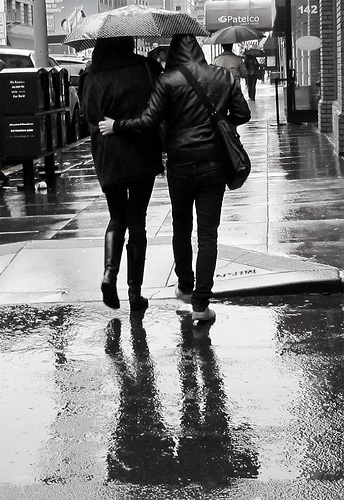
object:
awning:
[204, 1, 273, 33]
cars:
[0, 48, 81, 158]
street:
[260, 122, 327, 202]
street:
[9, 293, 339, 370]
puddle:
[2, 311, 69, 412]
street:
[0, 291, 342, 449]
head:
[89, 35, 135, 66]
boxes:
[0, 67, 70, 159]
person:
[77, 34, 163, 317]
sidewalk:
[0, 79, 343, 303]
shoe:
[190, 307, 218, 320]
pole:
[31, 0, 48, 70]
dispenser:
[0, 66, 70, 187]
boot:
[101, 227, 125, 309]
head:
[165, 34, 208, 69]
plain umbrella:
[199, 25, 266, 47]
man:
[211, 36, 249, 96]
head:
[221, 42, 234, 50]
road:
[280, 183, 326, 227]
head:
[248, 51, 254, 57]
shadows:
[177, 314, 258, 486]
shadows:
[105, 308, 178, 487]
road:
[4, 305, 342, 499]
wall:
[47, 78, 121, 124]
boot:
[125, 226, 150, 311]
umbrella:
[56, 5, 222, 58]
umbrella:
[64, 4, 209, 53]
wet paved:
[1, 70, 343, 498]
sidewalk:
[0, 83, 343, 499]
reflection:
[103, 307, 258, 498]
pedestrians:
[98, 29, 252, 323]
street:
[265, 383, 343, 499]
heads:
[156, 47, 167, 61]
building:
[276, 0, 342, 130]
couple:
[77, 23, 252, 321]